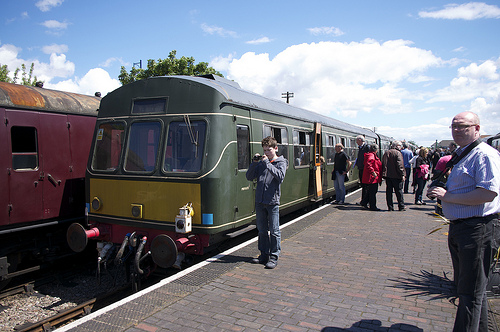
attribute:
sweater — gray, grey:
[246, 156, 288, 207]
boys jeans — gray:
[257, 205, 281, 254]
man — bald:
[431, 113, 499, 331]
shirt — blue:
[439, 142, 499, 219]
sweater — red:
[360, 153, 380, 186]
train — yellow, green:
[85, 72, 247, 265]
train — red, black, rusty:
[1, 82, 86, 288]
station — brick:
[291, 206, 444, 331]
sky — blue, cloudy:
[1, 1, 498, 52]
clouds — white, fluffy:
[229, 40, 434, 106]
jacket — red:
[360, 153, 375, 185]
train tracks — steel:
[0, 278, 117, 331]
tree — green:
[121, 48, 225, 79]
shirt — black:
[332, 151, 350, 173]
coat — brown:
[382, 149, 407, 182]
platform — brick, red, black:
[52, 178, 499, 330]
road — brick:
[54, 181, 497, 331]